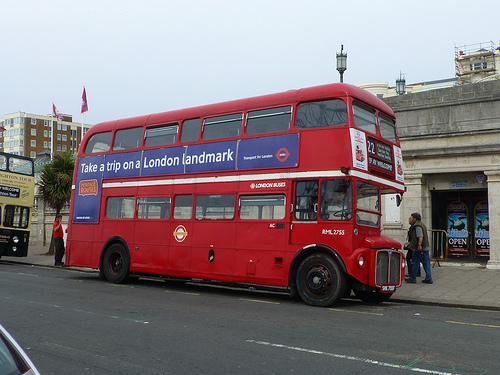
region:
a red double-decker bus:
[57, 76, 412, 306]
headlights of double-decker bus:
[355, 250, 405, 265]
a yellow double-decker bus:
[1, 145, 38, 262]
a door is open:
[420, 166, 496, 270]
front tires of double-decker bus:
[289, 240, 349, 311]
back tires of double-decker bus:
[96, 235, 131, 285]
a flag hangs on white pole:
[44, 95, 64, 160]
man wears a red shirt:
[48, 210, 68, 268]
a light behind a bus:
[331, 39, 354, 93]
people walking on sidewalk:
[401, 203, 443, 298]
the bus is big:
[61, 83, 410, 316]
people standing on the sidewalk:
[394, 204, 442, 287]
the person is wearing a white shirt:
[46, 210, 70, 265]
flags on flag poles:
[42, 77, 97, 163]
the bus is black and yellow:
[0, 144, 38, 266]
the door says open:
[436, 190, 471, 265]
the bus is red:
[62, 78, 410, 308]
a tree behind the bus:
[35, 145, 75, 260]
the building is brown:
[0, 107, 100, 157]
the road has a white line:
[231, 332, 458, 374]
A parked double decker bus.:
[59, 82, 400, 294]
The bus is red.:
[203, 233, 271, 267]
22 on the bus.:
[347, 134, 389, 176]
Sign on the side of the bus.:
[79, 130, 246, 173]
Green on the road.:
[397, 351, 477, 374]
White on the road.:
[249, 329, 358, 361]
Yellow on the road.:
[441, 311, 499, 335]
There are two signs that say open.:
[433, 211, 499, 267]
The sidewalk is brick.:
[409, 254, 499, 296]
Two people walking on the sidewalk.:
[399, 204, 451, 299]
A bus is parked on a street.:
[60, 80, 408, 310]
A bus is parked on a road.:
[60, 78, 410, 311]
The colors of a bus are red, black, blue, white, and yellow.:
[60, 80, 406, 311]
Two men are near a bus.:
[400, 207, 440, 289]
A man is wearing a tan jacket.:
[403, 217, 432, 253]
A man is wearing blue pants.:
[402, 244, 434, 286]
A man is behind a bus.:
[47, 211, 68, 268]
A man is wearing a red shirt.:
[48, 219, 66, 239]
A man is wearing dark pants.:
[47, 233, 69, 269]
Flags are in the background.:
[47, 85, 96, 134]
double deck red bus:
[24, 82, 406, 306]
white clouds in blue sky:
[24, 25, 74, 57]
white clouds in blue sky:
[137, 42, 165, 73]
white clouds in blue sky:
[52, 31, 129, 85]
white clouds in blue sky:
[132, 41, 193, 79]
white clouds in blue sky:
[238, 23, 269, 73]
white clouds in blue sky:
[178, 31, 240, 78]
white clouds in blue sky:
[367, 11, 417, 55]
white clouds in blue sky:
[241, 36, 289, 70]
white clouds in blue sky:
[118, 29, 160, 67]